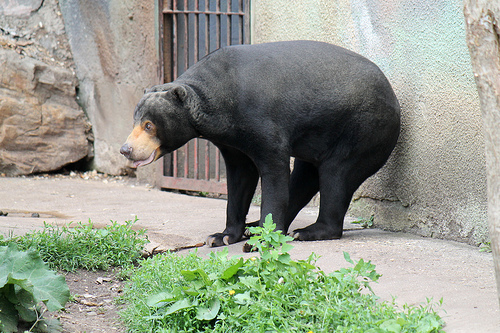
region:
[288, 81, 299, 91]
body of a bear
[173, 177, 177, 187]
bottom of a door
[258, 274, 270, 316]
leaves of a bush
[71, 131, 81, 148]
edge of a rock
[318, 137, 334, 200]
leg of a bear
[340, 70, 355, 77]
back of a bear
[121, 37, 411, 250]
a big black and tan bear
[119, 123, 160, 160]
a brown snout of a bear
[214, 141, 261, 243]
a black leg of a bear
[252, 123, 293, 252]
a black leg of a bear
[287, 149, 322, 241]
a black leg of a bear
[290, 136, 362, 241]
a black leg of a bear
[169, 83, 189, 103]
a black ear of a bear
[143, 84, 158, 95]
a black ear of a bear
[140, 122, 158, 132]
a black eye of a bear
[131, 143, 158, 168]
a pink tongue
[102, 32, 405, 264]
a black bear near a wall.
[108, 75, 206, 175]
the head of a black bear.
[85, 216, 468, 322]
a patch of green grass.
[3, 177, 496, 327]
a paved sidewalk.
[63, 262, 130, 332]
a patch of dirt.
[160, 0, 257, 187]
bars over a doorway.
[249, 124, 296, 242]
the left front leg of a bear.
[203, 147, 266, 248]
a black bear's right front leg.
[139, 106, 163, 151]
the left eye of a bear.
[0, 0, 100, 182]
a stone wall.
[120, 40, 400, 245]
a black bear in the zoo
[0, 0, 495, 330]
a black bear scratching his back on the wall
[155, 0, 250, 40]
metal bars on the door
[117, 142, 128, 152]
the bear has a black nose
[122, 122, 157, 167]
the bears muzzle is light brown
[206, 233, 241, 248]
the bears claws are white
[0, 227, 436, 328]
a patch of weeds in the ground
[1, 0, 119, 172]
a granite wall on the outside of the bear pen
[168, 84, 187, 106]
the bears black fur is on it's ears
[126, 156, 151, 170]
the bears tongue is pink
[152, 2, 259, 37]
Vertical metal bars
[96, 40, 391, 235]
Statue of black bear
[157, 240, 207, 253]
Crack in middle of sidewalk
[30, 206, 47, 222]
Grey stone on sidewalk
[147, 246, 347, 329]
Patch of grass and weeds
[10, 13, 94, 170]
Stone wall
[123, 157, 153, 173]
Tongue sticking out on bear statue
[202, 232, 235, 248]
Claws on bear statue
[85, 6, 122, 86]
Red swirl on concrete wall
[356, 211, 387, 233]
Weed growing in crack along wall